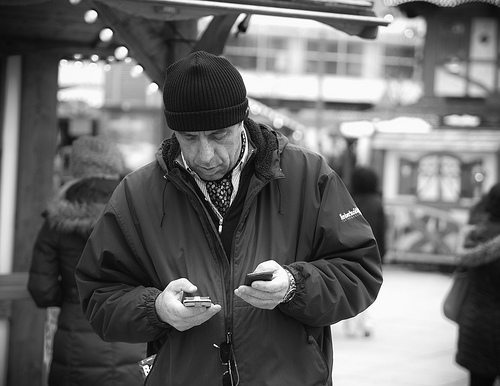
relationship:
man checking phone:
[89, 67, 349, 379] [165, 264, 226, 326]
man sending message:
[75, 50, 383, 379] [5, 35, 474, 365]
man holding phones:
[75, 50, 383, 379] [174, 272, 290, 329]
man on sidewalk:
[75, 50, 383, 379] [321, 273, 470, 382]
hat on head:
[161, 52, 251, 135] [162, 47, 250, 181]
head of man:
[162, 47, 250, 181] [75, 50, 383, 379]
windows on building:
[410, 149, 470, 206] [2, 0, 499, 271]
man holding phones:
[75, 50, 383, 379] [164, 257, 291, 314]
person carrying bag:
[441, 177, 498, 384] [437, 263, 472, 318]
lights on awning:
[65, 4, 158, 99] [12, 10, 379, 81]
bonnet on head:
[67, 137, 125, 181] [65, 135, 129, 182]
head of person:
[65, 135, 129, 182] [33, 135, 155, 384]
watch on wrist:
[268, 267, 311, 314] [281, 264, 301, 308]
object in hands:
[178, 293, 213, 310] [154, 274, 222, 332]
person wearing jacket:
[28, 139, 145, 386] [42, 173, 147, 340]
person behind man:
[28, 139, 145, 386] [136, 89, 381, 354]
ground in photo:
[343, 322, 407, 373] [2, 0, 497, 383]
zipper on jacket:
[224, 329, 232, 345] [77, 118, 383, 383]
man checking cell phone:
[75, 50, 383, 379] [183, 295, 212, 306]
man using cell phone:
[75, 50, 383, 379] [183, 295, 212, 308]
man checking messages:
[75, 50, 383, 379] [180, 268, 272, 306]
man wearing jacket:
[75, 50, 383, 379] [77, 118, 383, 383]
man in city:
[75, 50, 383, 379] [15, 14, 485, 369]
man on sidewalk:
[75, 50, 383, 379] [51, 266, 460, 383]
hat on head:
[164, 52, 242, 121] [159, 91, 246, 186]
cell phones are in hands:
[148, 257, 298, 336] [154, 257, 294, 332]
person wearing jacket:
[28, 139, 146, 382] [27, 127, 148, 373]